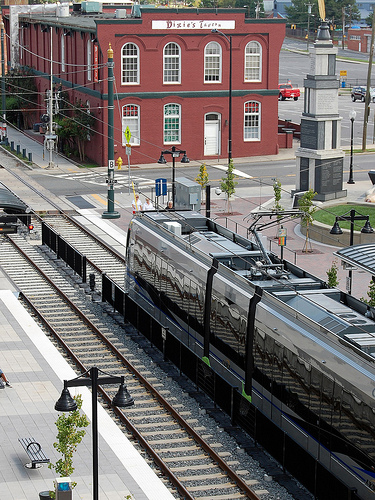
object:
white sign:
[151, 19, 236, 30]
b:
[110, 161, 113, 168]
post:
[101, 42, 120, 219]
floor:
[72, 216, 92, 226]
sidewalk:
[58, 178, 374, 302]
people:
[132, 193, 176, 211]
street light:
[157, 146, 189, 209]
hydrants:
[116, 156, 123, 169]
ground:
[277, 137, 298, 160]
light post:
[54, 367, 134, 500]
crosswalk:
[68, 171, 172, 189]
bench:
[18, 436, 50, 468]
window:
[162, 41, 182, 86]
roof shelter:
[332, 243, 374, 277]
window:
[203, 40, 224, 85]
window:
[120, 41, 141, 86]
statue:
[291, 0, 348, 201]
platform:
[0, 289, 174, 500]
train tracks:
[0, 165, 260, 500]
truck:
[278, 83, 301, 101]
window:
[162, 102, 182, 145]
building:
[0, 3, 300, 167]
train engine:
[155, 221, 258, 254]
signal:
[40, 80, 69, 170]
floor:
[84, 224, 106, 235]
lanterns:
[55, 387, 77, 411]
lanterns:
[112, 383, 134, 407]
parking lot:
[278, 94, 375, 145]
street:
[28, 153, 375, 196]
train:
[124, 208, 375, 500]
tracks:
[0, 234, 260, 500]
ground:
[0, 290, 138, 450]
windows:
[121, 103, 141, 147]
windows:
[242, 99, 262, 142]